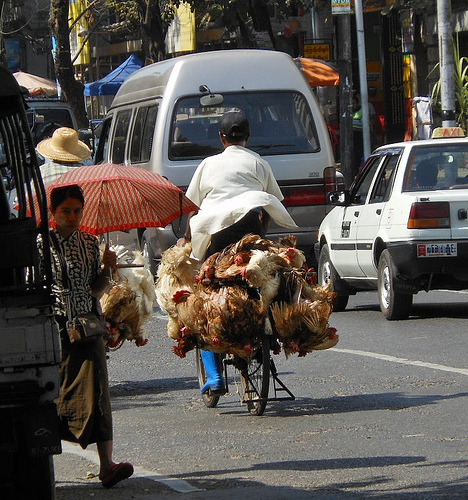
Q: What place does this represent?
A: It represents the sidewalk.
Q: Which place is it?
A: It is a sidewalk.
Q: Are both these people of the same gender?
A: No, they are both male and female.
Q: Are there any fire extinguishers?
A: No, there are no fire extinguishers.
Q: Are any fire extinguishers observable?
A: No, there are no fire extinguishers.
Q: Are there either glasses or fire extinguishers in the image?
A: No, there are no fire extinguishers or glasses.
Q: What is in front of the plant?
A: The pole is in front of the plant.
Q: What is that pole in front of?
A: The pole is in front of the plant.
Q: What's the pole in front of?
A: The pole is in front of the plant.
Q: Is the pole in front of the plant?
A: Yes, the pole is in front of the plant.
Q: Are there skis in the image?
A: No, there are no skis.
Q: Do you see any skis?
A: No, there are no skis.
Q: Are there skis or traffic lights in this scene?
A: No, there are no skis or traffic lights.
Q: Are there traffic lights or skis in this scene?
A: No, there are no skis or traffic lights.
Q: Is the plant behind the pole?
A: Yes, the plant is behind the pole.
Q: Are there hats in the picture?
A: Yes, there is a hat.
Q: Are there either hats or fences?
A: Yes, there is a hat.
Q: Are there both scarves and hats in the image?
A: No, there is a hat but no scarves.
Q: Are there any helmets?
A: No, there are no helmets.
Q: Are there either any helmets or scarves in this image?
A: No, there are no helmets or scarves.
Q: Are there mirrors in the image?
A: Yes, there is a mirror.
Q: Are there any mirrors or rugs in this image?
A: Yes, there is a mirror.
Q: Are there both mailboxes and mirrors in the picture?
A: No, there is a mirror but no mailboxes.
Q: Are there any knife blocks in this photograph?
A: No, there are no knife blocks.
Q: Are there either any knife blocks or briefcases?
A: No, there are no knife blocks or briefcases.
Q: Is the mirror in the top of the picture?
A: Yes, the mirror is in the top of the image.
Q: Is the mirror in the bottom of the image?
A: No, the mirror is in the top of the image.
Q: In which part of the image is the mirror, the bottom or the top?
A: The mirror is in the top of the image.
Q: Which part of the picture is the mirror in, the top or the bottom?
A: The mirror is in the top of the image.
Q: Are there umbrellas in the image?
A: Yes, there is an umbrella.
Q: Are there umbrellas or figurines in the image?
A: Yes, there is an umbrella.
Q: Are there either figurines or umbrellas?
A: Yes, there is an umbrella.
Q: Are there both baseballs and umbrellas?
A: No, there is an umbrella but no baseballs.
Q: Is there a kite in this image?
A: No, there are no kites.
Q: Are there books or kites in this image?
A: No, there are no kites or books.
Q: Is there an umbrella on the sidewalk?
A: Yes, there is an umbrella on the sidewalk.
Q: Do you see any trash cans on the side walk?
A: No, there is an umbrella on the side walk.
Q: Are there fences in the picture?
A: No, there are no fences.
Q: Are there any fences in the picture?
A: No, there are no fences.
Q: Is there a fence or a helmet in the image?
A: No, there are no fences or helmets.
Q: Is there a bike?
A: Yes, there is a bike.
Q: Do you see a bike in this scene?
A: Yes, there is a bike.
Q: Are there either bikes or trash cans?
A: Yes, there is a bike.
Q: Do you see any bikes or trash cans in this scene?
A: Yes, there is a bike.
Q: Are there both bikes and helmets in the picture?
A: No, there is a bike but no helmets.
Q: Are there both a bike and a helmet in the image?
A: No, there is a bike but no helmets.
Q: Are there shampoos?
A: No, there are no shampoos.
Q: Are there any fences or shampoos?
A: No, there are no shampoos or fences.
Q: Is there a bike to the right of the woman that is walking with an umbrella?
A: Yes, there is a bike to the right of the woman.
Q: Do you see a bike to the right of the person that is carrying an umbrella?
A: Yes, there is a bike to the right of the woman.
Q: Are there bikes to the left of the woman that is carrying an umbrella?
A: No, the bike is to the right of the woman.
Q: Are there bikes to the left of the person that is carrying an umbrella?
A: No, the bike is to the right of the woman.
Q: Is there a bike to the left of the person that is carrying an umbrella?
A: No, the bike is to the right of the woman.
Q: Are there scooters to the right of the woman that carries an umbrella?
A: No, there is a bike to the right of the woman.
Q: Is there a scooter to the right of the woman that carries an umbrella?
A: No, there is a bike to the right of the woman.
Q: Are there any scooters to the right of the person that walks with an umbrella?
A: No, there is a bike to the right of the woman.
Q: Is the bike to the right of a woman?
A: Yes, the bike is to the right of a woman.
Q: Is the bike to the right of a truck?
A: No, the bike is to the right of a woman.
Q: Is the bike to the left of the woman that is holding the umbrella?
A: No, the bike is to the right of the woman.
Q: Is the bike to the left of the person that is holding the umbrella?
A: No, the bike is to the right of the woman.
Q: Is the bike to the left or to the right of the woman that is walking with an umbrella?
A: The bike is to the right of the woman.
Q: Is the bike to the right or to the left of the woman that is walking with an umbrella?
A: The bike is to the right of the woman.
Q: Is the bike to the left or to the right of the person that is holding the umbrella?
A: The bike is to the right of the woman.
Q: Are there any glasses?
A: No, there are no glasses.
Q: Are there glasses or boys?
A: No, there are no glasses or boys.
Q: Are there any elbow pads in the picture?
A: No, there are no elbow pads.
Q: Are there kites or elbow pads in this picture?
A: No, there are no elbow pads or kites.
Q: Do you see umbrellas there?
A: Yes, there is an umbrella.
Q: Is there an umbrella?
A: Yes, there is an umbrella.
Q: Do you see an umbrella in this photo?
A: Yes, there is an umbrella.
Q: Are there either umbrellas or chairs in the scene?
A: Yes, there is an umbrella.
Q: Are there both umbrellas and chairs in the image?
A: No, there is an umbrella but no chairs.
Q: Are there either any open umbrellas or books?
A: Yes, there is an open umbrella.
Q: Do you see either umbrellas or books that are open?
A: Yes, the umbrella is open.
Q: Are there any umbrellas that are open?
A: Yes, there is an open umbrella.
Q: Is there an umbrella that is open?
A: Yes, there is an umbrella that is open.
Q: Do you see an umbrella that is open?
A: Yes, there is an umbrella that is open.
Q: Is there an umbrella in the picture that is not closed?
A: Yes, there is a open umbrella.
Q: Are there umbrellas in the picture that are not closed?
A: Yes, there is a open umbrella.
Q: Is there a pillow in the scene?
A: No, there are no pillows.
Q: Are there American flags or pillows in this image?
A: No, there are no pillows or American flags.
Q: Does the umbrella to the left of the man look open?
A: Yes, the umbrella is open.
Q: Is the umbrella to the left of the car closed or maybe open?
A: The umbrella is open.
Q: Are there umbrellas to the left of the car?
A: Yes, there is an umbrella to the left of the car.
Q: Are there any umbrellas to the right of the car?
A: No, the umbrella is to the left of the car.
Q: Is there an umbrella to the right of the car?
A: No, the umbrella is to the left of the car.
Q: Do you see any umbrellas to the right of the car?
A: No, the umbrella is to the left of the car.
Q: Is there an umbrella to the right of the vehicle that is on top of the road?
A: No, the umbrella is to the left of the car.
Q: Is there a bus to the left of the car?
A: No, there is an umbrella to the left of the car.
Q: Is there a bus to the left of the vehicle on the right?
A: No, there is an umbrella to the left of the car.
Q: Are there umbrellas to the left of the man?
A: Yes, there is an umbrella to the left of the man.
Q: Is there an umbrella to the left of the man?
A: Yes, there is an umbrella to the left of the man.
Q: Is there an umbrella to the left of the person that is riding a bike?
A: Yes, there is an umbrella to the left of the man.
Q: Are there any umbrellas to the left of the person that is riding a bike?
A: Yes, there is an umbrella to the left of the man.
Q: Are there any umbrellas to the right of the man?
A: No, the umbrella is to the left of the man.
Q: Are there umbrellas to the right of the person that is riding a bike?
A: No, the umbrella is to the left of the man.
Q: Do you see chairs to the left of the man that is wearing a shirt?
A: No, there is an umbrella to the left of the man.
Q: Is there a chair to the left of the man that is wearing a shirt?
A: No, there is an umbrella to the left of the man.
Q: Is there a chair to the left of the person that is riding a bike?
A: No, there is an umbrella to the left of the man.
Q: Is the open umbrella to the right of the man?
A: No, the umbrella is to the left of the man.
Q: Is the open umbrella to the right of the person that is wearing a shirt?
A: No, the umbrella is to the left of the man.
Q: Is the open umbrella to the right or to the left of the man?
A: The umbrella is to the left of the man.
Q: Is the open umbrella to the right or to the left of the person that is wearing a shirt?
A: The umbrella is to the left of the man.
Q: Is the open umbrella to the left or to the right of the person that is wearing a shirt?
A: The umbrella is to the left of the man.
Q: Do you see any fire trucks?
A: No, there are no fire trucks.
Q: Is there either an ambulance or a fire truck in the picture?
A: No, there are no fire trucks or ambulances.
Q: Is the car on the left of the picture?
A: No, the car is on the right of the image.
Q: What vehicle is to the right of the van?
A: The vehicle is a car.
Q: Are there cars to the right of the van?
A: Yes, there is a car to the right of the van.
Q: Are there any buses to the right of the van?
A: No, there is a car to the right of the van.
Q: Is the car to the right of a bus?
A: No, the car is to the right of a van.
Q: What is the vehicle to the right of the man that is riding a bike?
A: The vehicle is a car.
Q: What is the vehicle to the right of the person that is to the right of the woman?
A: The vehicle is a car.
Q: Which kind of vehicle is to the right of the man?
A: The vehicle is a car.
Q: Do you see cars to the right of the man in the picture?
A: Yes, there is a car to the right of the man.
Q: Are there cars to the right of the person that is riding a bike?
A: Yes, there is a car to the right of the man.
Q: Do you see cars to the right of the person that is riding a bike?
A: Yes, there is a car to the right of the man.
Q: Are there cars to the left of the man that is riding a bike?
A: No, the car is to the right of the man.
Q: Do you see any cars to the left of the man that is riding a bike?
A: No, the car is to the right of the man.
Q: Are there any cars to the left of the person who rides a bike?
A: No, the car is to the right of the man.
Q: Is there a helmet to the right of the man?
A: No, there is a car to the right of the man.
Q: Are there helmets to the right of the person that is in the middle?
A: No, there is a car to the right of the man.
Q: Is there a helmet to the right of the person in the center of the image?
A: No, there is a car to the right of the man.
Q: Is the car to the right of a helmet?
A: No, the car is to the right of a man.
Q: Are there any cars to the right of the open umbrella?
A: Yes, there is a car to the right of the umbrella.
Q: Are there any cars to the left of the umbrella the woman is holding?
A: No, the car is to the right of the umbrella.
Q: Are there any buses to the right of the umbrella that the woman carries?
A: No, there is a car to the right of the umbrella.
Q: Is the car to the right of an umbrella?
A: Yes, the car is to the right of an umbrella.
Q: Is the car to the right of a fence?
A: No, the car is to the right of an umbrella.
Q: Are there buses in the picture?
A: No, there are no buses.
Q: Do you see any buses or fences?
A: No, there are no buses or fences.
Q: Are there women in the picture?
A: Yes, there is a woman.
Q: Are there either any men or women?
A: Yes, there is a woman.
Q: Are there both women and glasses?
A: No, there is a woman but no glasses.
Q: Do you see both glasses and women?
A: No, there is a woman but no glasses.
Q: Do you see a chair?
A: No, there are no chairs.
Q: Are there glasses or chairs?
A: No, there are no chairs or glasses.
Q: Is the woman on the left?
A: Yes, the woman is on the left of the image.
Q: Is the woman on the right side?
A: No, the woman is on the left of the image.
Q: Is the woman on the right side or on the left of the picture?
A: The woman is on the left of the image.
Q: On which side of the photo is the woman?
A: The woman is on the left of the image.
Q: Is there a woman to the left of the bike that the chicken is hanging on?
A: Yes, there is a woman to the left of the bike.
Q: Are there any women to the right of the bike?
A: No, the woman is to the left of the bike.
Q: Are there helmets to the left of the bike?
A: No, there is a woman to the left of the bike.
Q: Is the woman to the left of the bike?
A: Yes, the woman is to the left of the bike.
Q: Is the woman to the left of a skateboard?
A: No, the woman is to the left of the bike.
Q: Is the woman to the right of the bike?
A: No, the woman is to the left of the bike.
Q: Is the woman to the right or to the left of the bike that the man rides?
A: The woman is to the left of the bike.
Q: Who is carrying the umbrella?
A: The woman is carrying the umbrella.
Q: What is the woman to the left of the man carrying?
A: The woman is carrying an umbrella.